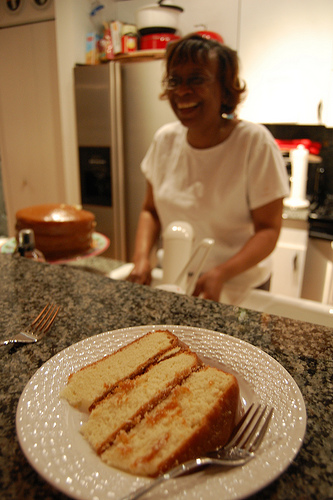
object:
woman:
[120, 29, 288, 302]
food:
[105, 363, 249, 474]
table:
[0, 247, 333, 498]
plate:
[15, 321, 314, 498]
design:
[17, 321, 309, 499]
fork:
[121, 399, 275, 499]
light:
[23, 368, 297, 499]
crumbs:
[147, 399, 181, 427]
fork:
[1, 297, 58, 346]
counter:
[0, 253, 333, 499]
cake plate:
[63, 230, 112, 264]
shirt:
[139, 108, 292, 289]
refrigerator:
[71, 59, 128, 261]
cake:
[13, 201, 97, 256]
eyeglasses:
[160, 67, 220, 90]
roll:
[284, 142, 314, 209]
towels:
[287, 145, 310, 200]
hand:
[192, 266, 227, 301]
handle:
[291, 252, 299, 273]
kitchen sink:
[117, 264, 333, 329]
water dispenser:
[76, 147, 113, 212]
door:
[73, 60, 119, 259]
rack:
[282, 141, 314, 212]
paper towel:
[288, 141, 311, 203]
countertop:
[0, 254, 333, 499]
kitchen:
[0, 0, 333, 498]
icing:
[87, 336, 173, 375]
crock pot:
[134, 2, 187, 35]